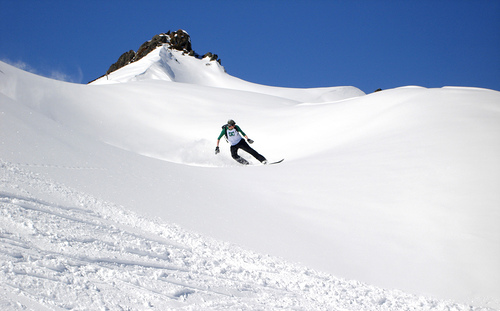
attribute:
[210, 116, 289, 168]
man — snowboarding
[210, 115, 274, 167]
person — skiing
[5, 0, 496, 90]
sky — clear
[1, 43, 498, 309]
snow — white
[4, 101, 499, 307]
snow — white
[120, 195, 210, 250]
snow — white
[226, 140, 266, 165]
pants — black